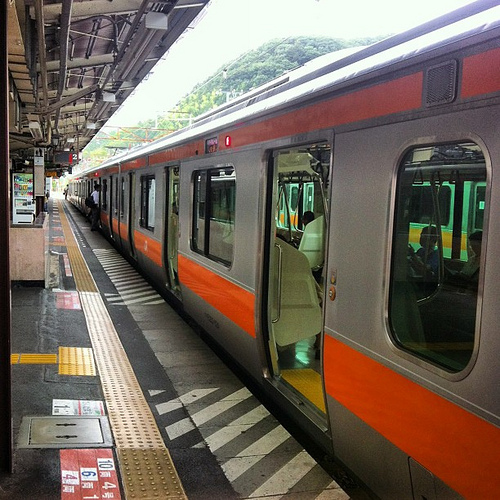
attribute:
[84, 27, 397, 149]
mountainside — woody